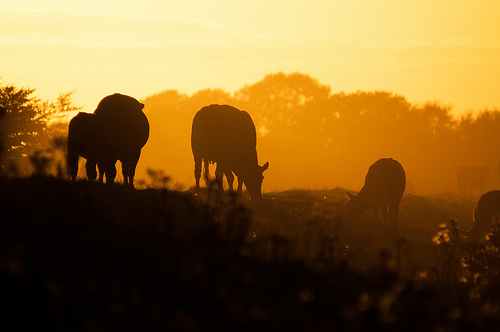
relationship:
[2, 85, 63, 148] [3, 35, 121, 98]
trees in background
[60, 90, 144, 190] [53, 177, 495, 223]
cows are in pasture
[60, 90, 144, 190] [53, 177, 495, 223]
cows in pasture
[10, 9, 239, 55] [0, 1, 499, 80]
clouds in sky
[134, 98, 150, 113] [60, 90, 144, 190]
ear on cows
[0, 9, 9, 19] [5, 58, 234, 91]
sun on horizon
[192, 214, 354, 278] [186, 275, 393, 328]
vegetation in front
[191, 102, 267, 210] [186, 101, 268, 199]
animal has a shilouette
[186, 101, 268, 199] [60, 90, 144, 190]
shilouette of cows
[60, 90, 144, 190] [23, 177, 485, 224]
cows are on hill